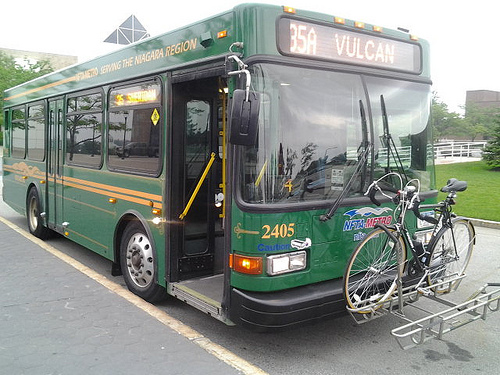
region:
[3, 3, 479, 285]
the bus is green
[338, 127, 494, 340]
bicycle on front of bus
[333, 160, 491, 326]
bike is on rack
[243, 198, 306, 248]
yellow number on front of bus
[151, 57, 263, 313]
bus doors are open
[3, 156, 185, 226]
gold stripe on side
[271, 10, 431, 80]
bus says 35a vulcan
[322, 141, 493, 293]
the bicycle is black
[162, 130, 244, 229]
yellow handle inside bus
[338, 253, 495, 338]
bike rack is silver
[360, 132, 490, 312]
A bike is visible.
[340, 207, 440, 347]
A bike is visible.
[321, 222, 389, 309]
A bike is visible.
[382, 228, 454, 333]
A bike is visible.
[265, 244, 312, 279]
the headlight of a vase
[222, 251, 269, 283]
the turn light of a bus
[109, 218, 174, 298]
the wheel of a bus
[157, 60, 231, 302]
the door of a bus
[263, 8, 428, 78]
the screen on the bus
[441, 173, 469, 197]
the seat of a bicycle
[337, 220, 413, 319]
the wheel of a bicycle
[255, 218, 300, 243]
numbers on the bus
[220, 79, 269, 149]
a side view mirror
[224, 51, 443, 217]
the windshield of a bus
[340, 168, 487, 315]
black metal bike on rack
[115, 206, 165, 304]
black tire and silver rim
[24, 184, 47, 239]
black tire and silver rim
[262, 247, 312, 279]
headlight on a bus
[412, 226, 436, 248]
headlight on a bus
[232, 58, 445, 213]
glass windshield on bus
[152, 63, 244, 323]
bus door is open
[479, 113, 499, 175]
small green tree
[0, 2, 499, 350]
a large green bus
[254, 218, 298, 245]
painted numbers on a bus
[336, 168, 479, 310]
bike on front of bus.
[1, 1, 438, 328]
the bus is green.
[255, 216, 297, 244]
number 2405 on bus.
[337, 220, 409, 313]
the wheel is round.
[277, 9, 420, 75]
sign on the bus.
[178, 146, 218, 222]
hand rail is yellow.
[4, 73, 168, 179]
windows on the bus.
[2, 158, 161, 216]
yellow stripe on bus.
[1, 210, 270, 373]
yellow line on ground.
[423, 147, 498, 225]
the grass is green.